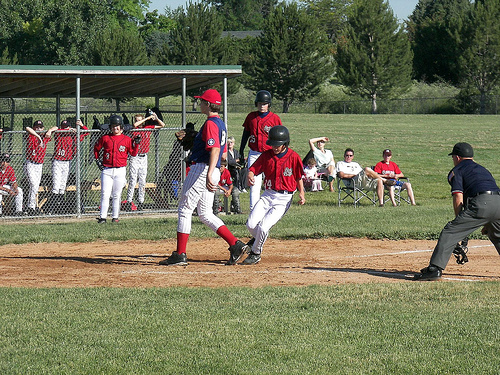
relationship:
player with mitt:
[418, 143, 490, 289] [439, 230, 483, 265]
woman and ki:
[306, 128, 335, 179] [372, 149, 397, 193]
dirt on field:
[289, 240, 388, 276] [127, 257, 385, 363]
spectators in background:
[2, 73, 215, 204] [2, 38, 472, 274]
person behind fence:
[130, 116, 157, 171] [55, 134, 88, 187]